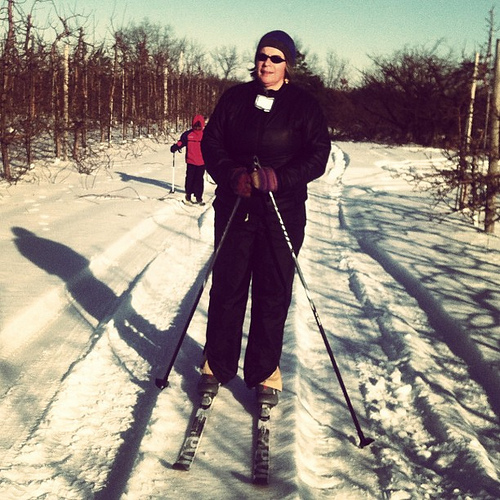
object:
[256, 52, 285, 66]
glasses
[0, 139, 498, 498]
trail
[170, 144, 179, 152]
hand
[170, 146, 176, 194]
pole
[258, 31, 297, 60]
hat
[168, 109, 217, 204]
skier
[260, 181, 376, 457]
ski pole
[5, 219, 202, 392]
shadow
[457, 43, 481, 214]
tree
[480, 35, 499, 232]
tree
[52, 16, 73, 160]
tree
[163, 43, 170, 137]
tree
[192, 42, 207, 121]
tree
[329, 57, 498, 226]
trail side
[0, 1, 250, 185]
trail side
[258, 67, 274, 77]
mouth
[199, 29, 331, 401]
person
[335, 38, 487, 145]
trees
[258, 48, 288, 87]
face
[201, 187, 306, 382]
pants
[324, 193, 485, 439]
shadows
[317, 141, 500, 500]
tracks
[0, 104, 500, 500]
snow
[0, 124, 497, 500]
ground